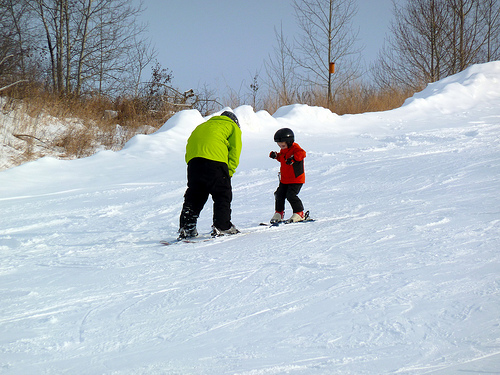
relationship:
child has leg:
[268, 127, 307, 223] [273, 185, 286, 215]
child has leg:
[268, 127, 307, 223] [284, 184, 306, 212]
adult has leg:
[174, 110, 242, 239] [175, 176, 209, 232]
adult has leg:
[174, 110, 242, 239] [209, 176, 234, 229]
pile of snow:
[401, 58, 496, 113] [335, 180, 476, 317]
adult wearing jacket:
[174, 110, 242, 239] [163, 120, 265, 164]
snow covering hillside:
[0, 61, 500, 373] [0, 58, 500, 368]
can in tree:
[330, 61, 335, 73] [281, 1, 377, 110]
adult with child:
[174, 110, 242, 239] [261, 122, 315, 229]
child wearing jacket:
[268, 127, 307, 223] [273, 142, 306, 184]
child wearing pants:
[265, 127, 310, 219] [270, 178, 302, 214]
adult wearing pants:
[174, 110, 242, 239] [176, 154, 233, 233]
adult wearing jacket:
[174, 102, 254, 239] [184, 114, 242, 174]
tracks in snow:
[0, 90, 500, 370] [0, 61, 500, 373]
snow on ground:
[0, 61, 500, 373] [1, 102, 497, 370]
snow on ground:
[215, 272, 277, 334] [337, 304, 459, 364]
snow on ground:
[13, 228, 107, 265] [11, 253, 488, 361]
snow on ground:
[0, 61, 500, 373] [6, 134, 494, 370]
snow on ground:
[335, 179, 442, 322] [1, 60, 498, 371]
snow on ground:
[381, 165, 433, 230] [1, 60, 498, 371]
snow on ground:
[329, 171, 478, 324] [1, 60, 498, 371]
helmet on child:
[270, 116, 312, 143] [229, 77, 366, 244]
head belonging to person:
[271, 125, 295, 149] [266, 128, 311, 221]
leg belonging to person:
[272, 190, 284, 217] [266, 127, 303, 167]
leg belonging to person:
[209, 180, 241, 235] [179, 104, 247, 237]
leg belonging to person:
[213, 188, 232, 229] [171, 89, 271, 230]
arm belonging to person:
[269, 149, 305, 174] [252, 119, 311, 230]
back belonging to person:
[188, 116, 234, 146] [153, 76, 246, 236]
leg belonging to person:
[213, 188, 232, 229] [162, 109, 249, 253]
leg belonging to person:
[175, 169, 214, 239] [162, 109, 249, 253]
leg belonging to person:
[288, 182, 303, 222] [253, 126, 315, 244]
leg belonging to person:
[270, 184, 289, 221] [162, 109, 249, 253]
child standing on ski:
[268, 127, 307, 223] [255, 211, 290, 225]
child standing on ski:
[268, 127, 307, 223] [270, 210, 314, 224]